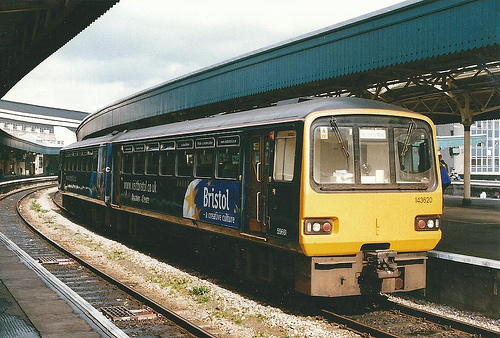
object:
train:
[44, 101, 448, 309]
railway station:
[1, 2, 498, 337]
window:
[216, 136, 242, 181]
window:
[193, 138, 216, 178]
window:
[174, 139, 195, 179]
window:
[160, 142, 176, 176]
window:
[148, 142, 159, 177]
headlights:
[304, 217, 336, 234]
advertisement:
[119, 171, 243, 224]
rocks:
[29, 185, 358, 337]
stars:
[182, 180, 202, 218]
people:
[14, 153, 27, 176]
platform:
[2, 133, 60, 191]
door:
[241, 131, 276, 230]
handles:
[255, 158, 263, 184]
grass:
[26, 196, 257, 338]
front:
[298, 97, 444, 300]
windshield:
[308, 115, 437, 193]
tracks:
[1, 174, 452, 337]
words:
[199, 184, 234, 208]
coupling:
[308, 247, 430, 296]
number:
[413, 195, 434, 204]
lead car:
[108, 96, 453, 305]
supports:
[375, 72, 494, 210]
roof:
[76, 96, 432, 145]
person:
[435, 146, 453, 200]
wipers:
[327, 115, 351, 160]